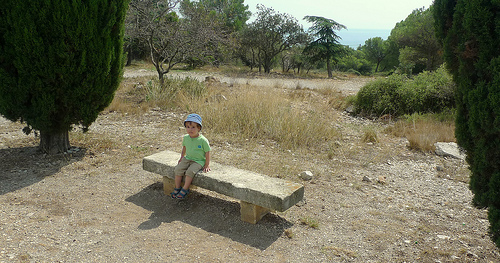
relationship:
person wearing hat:
[172, 113, 216, 205] [185, 114, 205, 126]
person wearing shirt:
[172, 113, 216, 205] [178, 133, 210, 170]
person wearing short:
[172, 113, 216, 205] [177, 157, 204, 176]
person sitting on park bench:
[172, 113, 216, 205] [140, 146, 304, 227]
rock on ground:
[301, 167, 316, 182] [0, 55, 500, 262]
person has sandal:
[172, 113, 216, 205] [173, 183, 191, 198]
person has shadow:
[172, 113, 216, 205] [130, 175, 292, 258]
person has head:
[172, 113, 216, 205] [182, 113, 207, 139]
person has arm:
[172, 113, 216, 205] [199, 138, 218, 175]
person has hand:
[172, 113, 216, 205] [201, 161, 213, 174]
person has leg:
[172, 113, 216, 205] [176, 164, 205, 196]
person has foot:
[172, 113, 216, 205] [170, 185, 183, 197]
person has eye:
[172, 113, 216, 205] [186, 121, 192, 130]